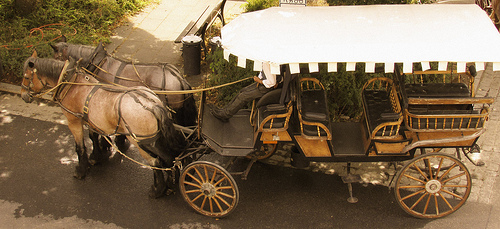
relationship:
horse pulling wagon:
[18, 50, 185, 200] [178, 2, 499, 222]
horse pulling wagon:
[48, 35, 201, 132] [178, 2, 499, 222]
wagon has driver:
[178, 2, 499, 222] [206, 55, 284, 125]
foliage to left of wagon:
[3, 3, 153, 90] [178, 2, 499, 222]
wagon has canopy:
[178, 2, 499, 222] [219, 4, 500, 74]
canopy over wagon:
[219, 4, 500, 74] [178, 2, 499, 222]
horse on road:
[18, 50, 185, 200] [0, 89, 499, 227]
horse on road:
[48, 35, 201, 132] [0, 89, 499, 227]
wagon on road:
[178, 2, 499, 222] [0, 89, 499, 227]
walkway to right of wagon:
[396, 50, 499, 207] [178, 2, 499, 222]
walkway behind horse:
[99, 0, 243, 144] [18, 50, 185, 200]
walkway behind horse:
[99, 0, 243, 144] [48, 35, 201, 132]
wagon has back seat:
[178, 2, 499, 222] [400, 70, 474, 104]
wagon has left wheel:
[178, 2, 499, 222] [176, 160, 241, 218]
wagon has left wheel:
[178, 2, 499, 222] [391, 151, 473, 222]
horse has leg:
[18, 50, 185, 200] [70, 120, 90, 181]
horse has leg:
[18, 50, 185, 200] [85, 127, 104, 167]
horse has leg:
[18, 50, 185, 200] [151, 155, 168, 202]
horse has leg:
[18, 50, 185, 200] [163, 164, 177, 196]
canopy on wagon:
[219, 4, 500, 74] [178, 2, 499, 222]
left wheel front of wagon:
[176, 160, 241, 218] [178, 2, 499, 222]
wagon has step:
[178, 2, 499, 222] [347, 185, 359, 205]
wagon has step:
[178, 2, 499, 222] [337, 162, 364, 183]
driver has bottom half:
[206, 55, 284, 125] [212, 81, 280, 123]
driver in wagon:
[206, 55, 284, 125] [178, 2, 499, 222]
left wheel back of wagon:
[391, 151, 473, 222] [178, 2, 499, 222]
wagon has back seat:
[178, 2, 499, 222] [402, 104, 489, 135]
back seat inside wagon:
[400, 70, 474, 104] [178, 2, 499, 222]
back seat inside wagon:
[402, 104, 489, 135] [178, 2, 499, 222]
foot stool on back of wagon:
[463, 144, 487, 168] [178, 2, 499, 222]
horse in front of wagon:
[18, 50, 185, 200] [178, 2, 499, 222]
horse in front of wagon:
[48, 35, 201, 132] [178, 2, 499, 222]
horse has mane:
[18, 50, 185, 200] [22, 55, 77, 82]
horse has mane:
[48, 35, 201, 132] [57, 42, 102, 63]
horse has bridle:
[18, 50, 185, 200] [19, 52, 49, 98]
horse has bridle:
[48, 35, 201, 132] [55, 44, 69, 61]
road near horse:
[0, 89, 499, 227] [18, 50, 185, 200]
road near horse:
[0, 89, 499, 227] [48, 35, 201, 132]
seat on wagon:
[363, 87, 396, 135] [178, 2, 499, 222]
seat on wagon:
[300, 89, 328, 135] [178, 2, 499, 222]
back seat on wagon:
[400, 70, 474, 104] [178, 2, 499, 222]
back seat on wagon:
[402, 104, 489, 135] [178, 2, 499, 222]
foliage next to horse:
[3, 3, 153, 90] [18, 50, 185, 200]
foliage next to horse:
[3, 3, 153, 90] [48, 35, 201, 132]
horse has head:
[18, 50, 185, 200] [20, 49, 60, 106]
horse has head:
[48, 35, 201, 132] [48, 33, 83, 61]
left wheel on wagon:
[176, 160, 241, 218] [178, 2, 499, 222]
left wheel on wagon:
[391, 151, 473, 222] [178, 2, 499, 222]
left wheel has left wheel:
[176, 160, 241, 218] [176, 160, 241, 218]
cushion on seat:
[303, 88, 329, 121] [300, 89, 328, 135]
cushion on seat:
[362, 88, 395, 136] [363, 87, 396, 135]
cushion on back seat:
[402, 79, 471, 99] [400, 70, 474, 104]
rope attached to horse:
[68, 73, 259, 97] [18, 50, 185, 200]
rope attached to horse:
[68, 73, 259, 97] [48, 35, 201, 132]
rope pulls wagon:
[68, 73, 259, 97] [178, 2, 499, 222]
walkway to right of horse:
[99, 0, 243, 144] [18, 50, 185, 200]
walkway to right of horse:
[99, 0, 243, 144] [48, 35, 201, 132]